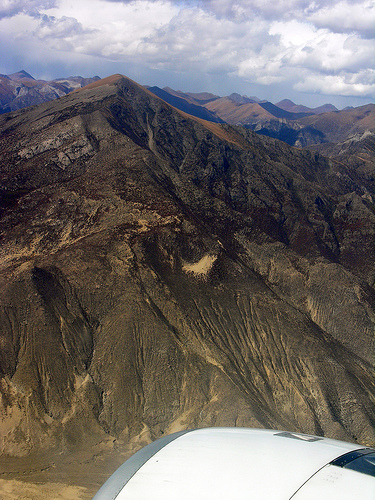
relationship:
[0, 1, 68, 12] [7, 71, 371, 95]
cloud in sky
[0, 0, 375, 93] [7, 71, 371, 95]
cloud in sky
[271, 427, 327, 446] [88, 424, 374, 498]
sticker on airplane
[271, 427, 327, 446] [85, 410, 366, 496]
sticker on airplane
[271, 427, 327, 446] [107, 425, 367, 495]
sticker on plane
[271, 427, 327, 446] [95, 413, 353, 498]
sticker on plane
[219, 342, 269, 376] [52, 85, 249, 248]
line on mountain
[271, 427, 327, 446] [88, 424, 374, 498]
sticker on top of airplane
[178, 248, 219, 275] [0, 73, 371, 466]
area is on mountain